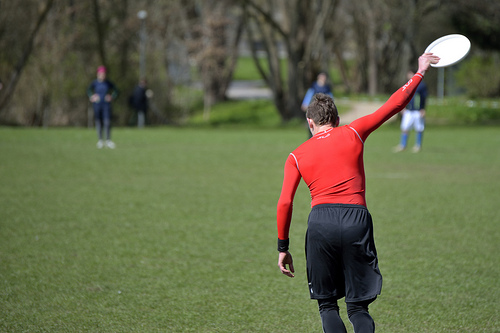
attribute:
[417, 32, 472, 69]
frisbee — white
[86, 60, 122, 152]
woman — has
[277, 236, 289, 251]
wrist band — on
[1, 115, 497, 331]
grass — green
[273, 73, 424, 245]
shirt — on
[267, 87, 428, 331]
guy — with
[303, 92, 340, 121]
hair — on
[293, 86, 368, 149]
hair — brown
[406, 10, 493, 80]
frisbee — white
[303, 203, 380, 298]
shorts — on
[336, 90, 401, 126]
pathway — dirt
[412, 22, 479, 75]
frisbee — with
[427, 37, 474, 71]
frisbee — white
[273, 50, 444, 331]
man — has on, with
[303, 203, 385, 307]
shorts — blue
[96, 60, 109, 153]
people — on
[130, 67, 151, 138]
people — on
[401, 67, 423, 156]
people — on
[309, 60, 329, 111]
people — on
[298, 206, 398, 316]
shorts — black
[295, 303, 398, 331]
socks — black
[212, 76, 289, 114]
path — grey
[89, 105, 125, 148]
jeans — blue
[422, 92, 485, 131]
plants — wild